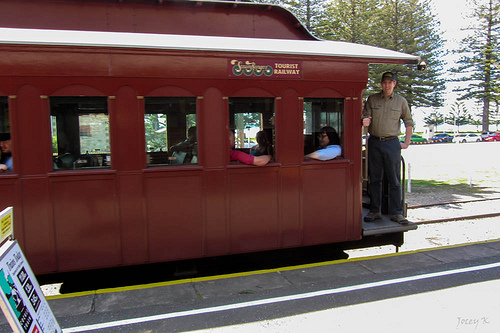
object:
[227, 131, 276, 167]
man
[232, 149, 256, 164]
shirt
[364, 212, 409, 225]
grey shoes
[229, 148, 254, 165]
pink shirt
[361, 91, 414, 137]
shirt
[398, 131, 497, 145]
parking area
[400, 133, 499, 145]
vehicles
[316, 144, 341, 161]
shirt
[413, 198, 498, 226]
track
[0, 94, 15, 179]
window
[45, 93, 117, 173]
window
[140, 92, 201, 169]
window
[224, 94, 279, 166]
window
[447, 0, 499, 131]
tree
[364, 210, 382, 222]
shoe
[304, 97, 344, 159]
window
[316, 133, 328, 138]
glasses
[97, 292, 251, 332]
sidewalk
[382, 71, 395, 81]
hat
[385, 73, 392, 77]
lettering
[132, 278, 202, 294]
yellow line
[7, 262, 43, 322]
times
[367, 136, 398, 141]
belt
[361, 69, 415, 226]
man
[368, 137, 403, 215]
blue pants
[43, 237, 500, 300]
line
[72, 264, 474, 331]
train platform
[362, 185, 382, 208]
stairs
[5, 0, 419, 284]
red train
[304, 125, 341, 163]
lady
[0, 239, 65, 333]
sign